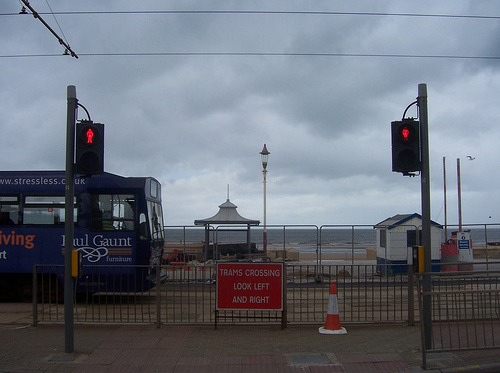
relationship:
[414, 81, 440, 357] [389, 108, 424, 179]
pole has a traffic light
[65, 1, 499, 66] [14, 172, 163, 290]
cables above tram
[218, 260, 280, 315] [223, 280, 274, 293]
sign reading look left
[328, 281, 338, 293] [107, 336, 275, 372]
cone on sidewalk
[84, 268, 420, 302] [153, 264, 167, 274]
gate has post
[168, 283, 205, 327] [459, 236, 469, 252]
road has warning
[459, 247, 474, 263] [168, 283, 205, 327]
board on road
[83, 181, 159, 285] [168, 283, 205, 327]
bus on road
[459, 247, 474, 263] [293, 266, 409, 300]
board attached to fence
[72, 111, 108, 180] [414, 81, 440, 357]
signals attached to pole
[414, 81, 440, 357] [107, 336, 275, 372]
pole on sidewalk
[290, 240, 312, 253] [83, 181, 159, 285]
water behind bus